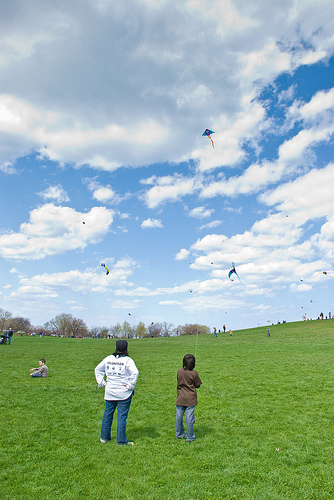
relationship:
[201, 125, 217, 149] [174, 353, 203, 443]
kite being flown by boy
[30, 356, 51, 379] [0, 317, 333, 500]
boy sitting in grass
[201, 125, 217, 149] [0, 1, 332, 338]
kite in sky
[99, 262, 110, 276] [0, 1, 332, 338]
kite in sky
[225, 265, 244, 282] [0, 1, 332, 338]
kite in sky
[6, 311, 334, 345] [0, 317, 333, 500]
people are walking on grass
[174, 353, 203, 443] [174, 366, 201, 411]
boy wearing a brown shirt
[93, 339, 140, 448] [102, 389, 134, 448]
person wearing jeans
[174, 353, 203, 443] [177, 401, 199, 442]
boy wearing jeans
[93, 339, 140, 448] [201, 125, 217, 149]
person flying a kite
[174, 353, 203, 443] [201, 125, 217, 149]
boy flying a kite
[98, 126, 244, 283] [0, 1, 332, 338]
kites are flying in sky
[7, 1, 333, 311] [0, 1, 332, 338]
clouds are visible in sky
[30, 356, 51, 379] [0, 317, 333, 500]
boy sitting down in grass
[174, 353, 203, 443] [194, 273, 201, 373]
boy holding onto a string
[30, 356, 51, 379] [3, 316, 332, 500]
boy sitting on ground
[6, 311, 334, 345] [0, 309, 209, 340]
people are standing by trees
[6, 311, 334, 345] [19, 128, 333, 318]
people are flying kites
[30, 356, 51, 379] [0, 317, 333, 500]
boy sitting on grass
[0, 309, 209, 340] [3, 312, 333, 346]
trees are on hill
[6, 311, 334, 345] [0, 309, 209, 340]
people are standing before trees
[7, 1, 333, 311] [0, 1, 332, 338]
clouds are in sky